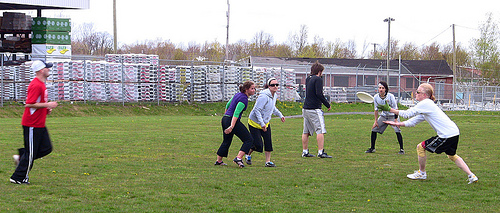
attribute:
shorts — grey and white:
[302, 108, 327, 136]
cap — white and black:
[29, 59, 52, 73]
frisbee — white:
[352, 86, 414, 128]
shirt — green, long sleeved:
[300, 74, 331, 109]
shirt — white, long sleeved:
[398, 97, 460, 138]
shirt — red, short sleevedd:
[425, 106, 467, 145]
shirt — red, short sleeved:
[21, 71, 62, 130]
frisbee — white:
[346, 86, 381, 114]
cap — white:
[31, 59, 53, 74]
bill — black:
[46, 62, 54, 66]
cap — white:
[31, 55, 56, 72]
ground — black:
[251, 105, 316, 152]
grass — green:
[204, 183, 303, 207]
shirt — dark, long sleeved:
[291, 70, 331, 119]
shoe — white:
[405, 169, 427, 181]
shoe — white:
[466, 174, 477, 184]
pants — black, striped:
[10, 123, 53, 183]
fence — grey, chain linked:
[6, 48, 498, 118]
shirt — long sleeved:
[300, 73, 328, 118]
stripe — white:
[26, 122, 36, 187]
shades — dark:
[265, 80, 281, 90]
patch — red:
[417, 138, 433, 158]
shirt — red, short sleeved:
[15, 73, 52, 130]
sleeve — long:
[231, 99, 245, 122]